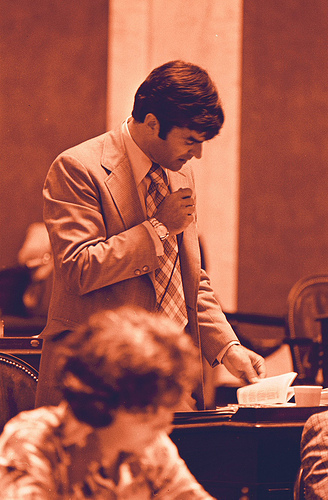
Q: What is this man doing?
A: Talking.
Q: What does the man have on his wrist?
A: Watch.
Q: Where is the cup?
A: Desk.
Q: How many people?
A: 3.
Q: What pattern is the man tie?
A: Plaid.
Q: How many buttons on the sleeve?
A: 2.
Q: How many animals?
A: None.